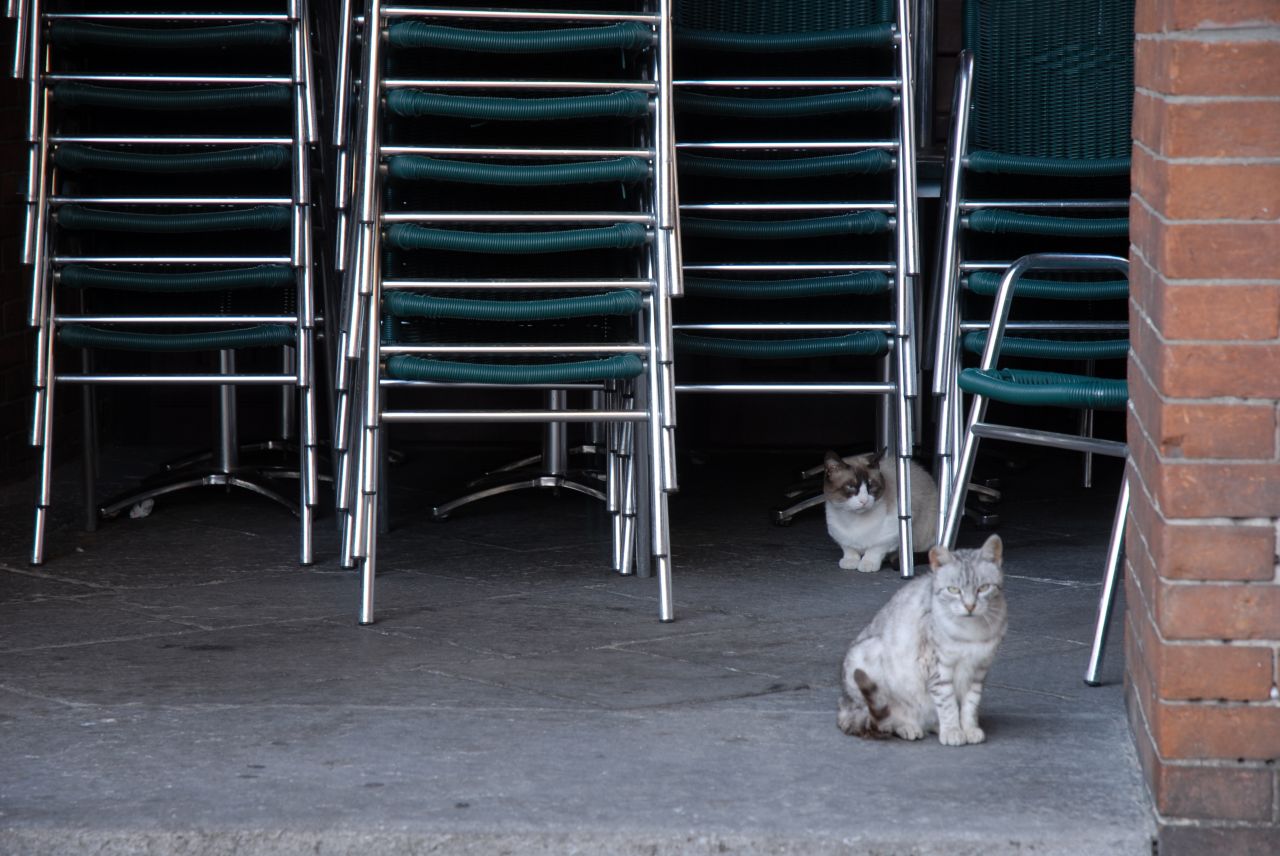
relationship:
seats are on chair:
[39, 7, 309, 374] [339, 25, 703, 460]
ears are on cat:
[817, 448, 887, 481] [820, 446, 951, 574]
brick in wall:
[1158, 34, 1276, 105] [1091, 14, 1277, 812]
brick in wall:
[1158, 157, 1276, 221] [1091, 14, 1277, 812]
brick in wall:
[1158, 274, 1276, 345] [1091, 14, 1277, 812]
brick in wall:
[1158, 398, 1276, 462] [1091, 14, 1277, 812]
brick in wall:
[1158, 514, 1276, 576] [1091, 14, 1277, 812]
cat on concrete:
[832, 534, 1018, 758] [560, 587, 1017, 749]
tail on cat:
[834, 670, 893, 739] [851, 546, 1021, 727]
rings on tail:
[842, 530, 1010, 740] [842, 530, 1010, 740]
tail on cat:
[842, 530, 1010, 740] [842, 530, 1010, 740]